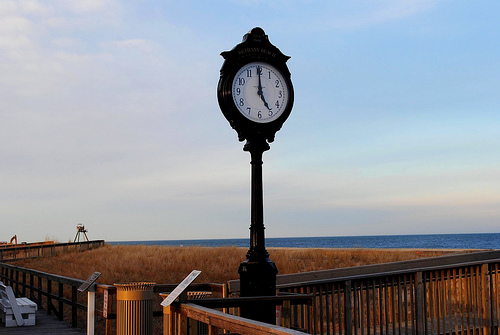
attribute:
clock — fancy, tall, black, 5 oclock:
[218, 24, 301, 329]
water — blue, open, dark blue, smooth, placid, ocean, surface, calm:
[108, 234, 499, 250]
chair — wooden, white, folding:
[1, 282, 38, 329]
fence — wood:
[3, 244, 499, 335]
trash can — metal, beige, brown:
[110, 278, 155, 334]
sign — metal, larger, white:
[162, 264, 202, 308]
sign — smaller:
[76, 272, 106, 293]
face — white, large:
[231, 60, 289, 123]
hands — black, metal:
[254, 67, 273, 115]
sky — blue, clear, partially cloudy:
[1, 3, 496, 244]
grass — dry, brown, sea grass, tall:
[29, 241, 470, 277]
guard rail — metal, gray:
[6, 262, 114, 325]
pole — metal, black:
[239, 140, 281, 324]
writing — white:
[236, 46, 284, 58]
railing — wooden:
[167, 291, 321, 334]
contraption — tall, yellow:
[72, 222, 92, 244]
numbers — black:
[234, 68, 284, 122]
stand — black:
[233, 256, 279, 325]